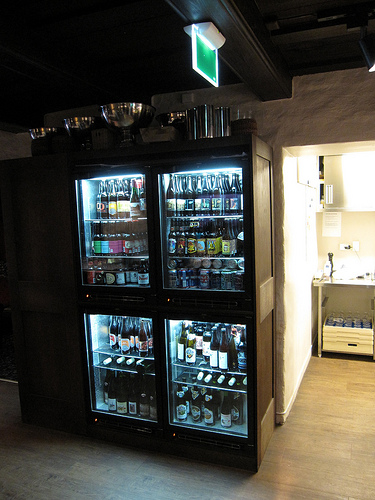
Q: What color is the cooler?
A: Black.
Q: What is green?
A: Sign.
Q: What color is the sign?
A: Green.